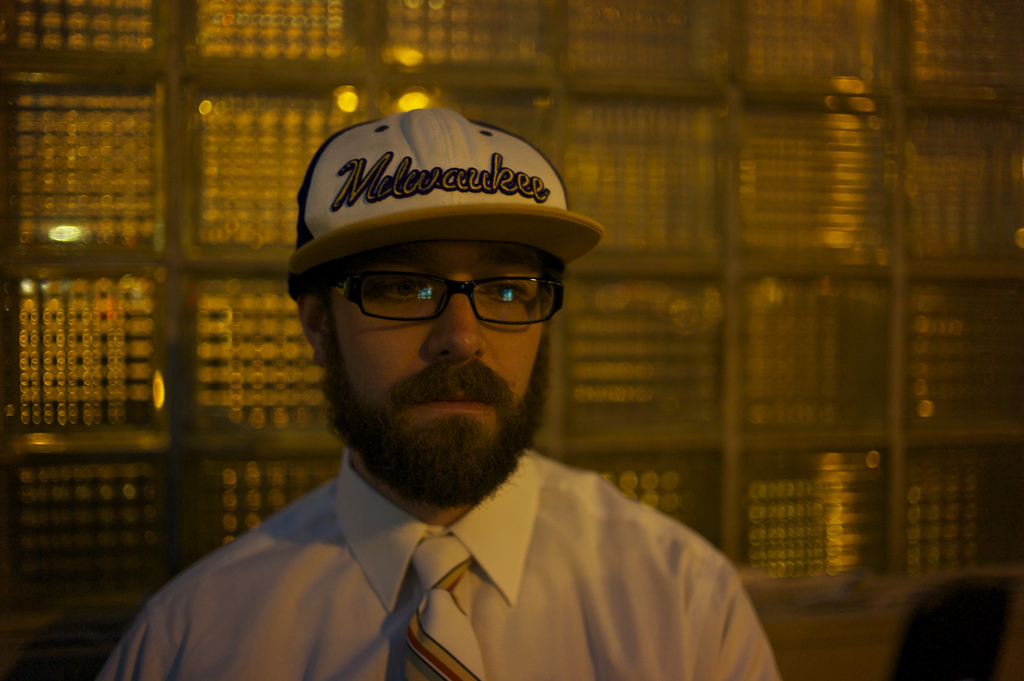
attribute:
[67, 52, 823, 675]
man — glass block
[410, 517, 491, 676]
tie — colorful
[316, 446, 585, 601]
collar — white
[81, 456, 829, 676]
shirt — white, long sleeve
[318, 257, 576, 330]
glasses — black framed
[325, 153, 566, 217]
cap — baseball, black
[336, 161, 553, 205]
letters — yellow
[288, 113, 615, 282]
cap — baseball